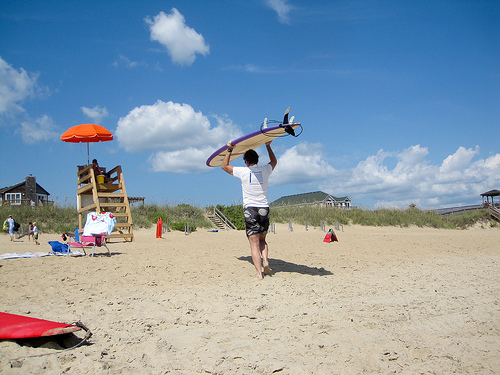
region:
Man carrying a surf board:
[183, 75, 335, 294]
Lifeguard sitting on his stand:
[37, 88, 152, 277]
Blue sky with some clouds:
[327, 12, 494, 194]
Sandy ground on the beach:
[364, 250, 482, 372]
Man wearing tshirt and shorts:
[218, 142, 290, 273]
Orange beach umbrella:
[47, 105, 117, 164]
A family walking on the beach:
[7, 202, 47, 249]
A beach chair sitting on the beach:
[48, 214, 129, 269]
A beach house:
[272, 185, 359, 227]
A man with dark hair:
[233, 132, 273, 177]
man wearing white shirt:
[231, 159, 279, 206]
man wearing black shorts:
[246, 204, 276, 242]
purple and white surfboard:
[196, 114, 318, 173]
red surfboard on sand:
[11, 306, 100, 344]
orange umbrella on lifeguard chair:
[58, 115, 128, 157]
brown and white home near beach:
[2, 160, 53, 215]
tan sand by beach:
[373, 235, 478, 357]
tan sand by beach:
[109, 283, 376, 368]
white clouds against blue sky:
[18, 11, 243, 121]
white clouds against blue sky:
[301, 25, 476, 180]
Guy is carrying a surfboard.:
[194, 102, 316, 287]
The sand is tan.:
[203, 304, 368, 359]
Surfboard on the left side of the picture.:
[6, 298, 104, 365]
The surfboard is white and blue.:
[196, 121, 309, 172]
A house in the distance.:
[277, 184, 359, 223]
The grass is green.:
[303, 207, 410, 224]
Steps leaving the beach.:
[184, 197, 234, 240]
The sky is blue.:
[321, 27, 440, 134]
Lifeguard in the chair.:
[68, 156, 140, 223]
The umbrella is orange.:
[54, 110, 115, 162]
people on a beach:
[4, 1, 470, 371]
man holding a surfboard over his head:
[198, 101, 311, 283]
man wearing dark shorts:
[237, 202, 275, 239]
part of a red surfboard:
[0, 300, 92, 362]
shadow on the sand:
[222, 243, 339, 288]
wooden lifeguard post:
[71, 151, 139, 238]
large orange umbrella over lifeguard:
[56, 111, 123, 191]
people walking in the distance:
[2, 208, 64, 265]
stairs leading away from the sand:
[193, 201, 248, 256]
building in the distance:
[4, 170, 54, 215]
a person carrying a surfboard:
[202, 105, 302, 283]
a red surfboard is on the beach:
[2, 306, 92, 357]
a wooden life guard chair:
[72, 158, 132, 238]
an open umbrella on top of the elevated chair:
[60, 120, 133, 238]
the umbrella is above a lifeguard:
[58, 118, 116, 189]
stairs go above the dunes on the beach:
[197, 205, 233, 233]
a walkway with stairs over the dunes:
[422, 186, 494, 229]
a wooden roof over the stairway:
[475, 185, 496, 225]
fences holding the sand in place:
[170, 215, 350, 235]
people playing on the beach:
[3, 213, 45, 248]